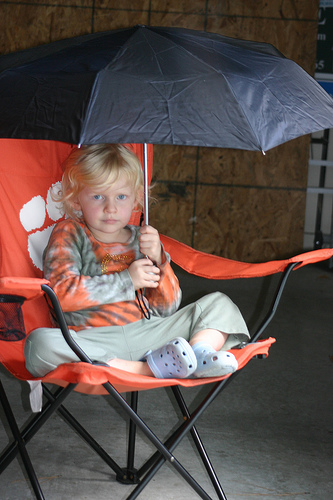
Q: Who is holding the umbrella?
A: A small child is holding the umbrella.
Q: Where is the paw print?
A: Orange chair.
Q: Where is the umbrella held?
A: Girl's hands.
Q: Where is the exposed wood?
A: Behind girl.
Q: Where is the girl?
A: On orange chair.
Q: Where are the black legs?
A: Under chair.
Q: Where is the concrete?
A: On the ground.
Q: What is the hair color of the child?
A: Blonde.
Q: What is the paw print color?
A: White.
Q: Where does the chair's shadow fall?
A: Behind it.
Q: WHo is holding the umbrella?
A: A child.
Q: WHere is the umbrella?
A: In the child's hands.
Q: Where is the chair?
A: ON the ground.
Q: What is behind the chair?
A: Plywood.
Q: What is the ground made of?
A: Concrete.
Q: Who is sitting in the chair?
A: The child.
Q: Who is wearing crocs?
A: The child.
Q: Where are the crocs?
A: On the child's feet.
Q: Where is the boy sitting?
A: In a chair.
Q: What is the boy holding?
A: Umbrella.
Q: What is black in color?
A: The umbrella.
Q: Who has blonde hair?
A: The boy.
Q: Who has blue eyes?
A: A boy.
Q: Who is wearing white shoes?
A: Boy sitting down.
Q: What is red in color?
A: The chair.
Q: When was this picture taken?
A: During the day.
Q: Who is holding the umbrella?
A: Little boy.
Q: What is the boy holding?
A: An umbrella.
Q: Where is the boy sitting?
A: In a chair.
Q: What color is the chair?
A: Orange.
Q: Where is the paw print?
A: Back of the chair.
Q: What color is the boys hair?
A: Blonde.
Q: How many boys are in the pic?
A: 1.